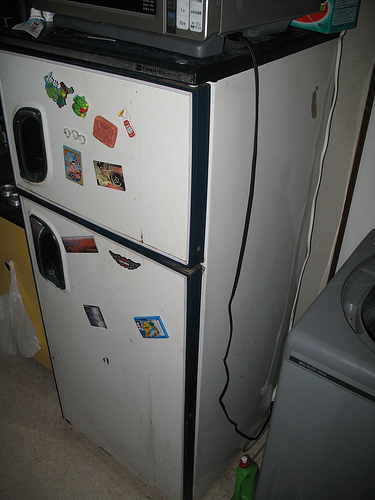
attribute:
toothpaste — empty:
[15, 6, 73, 46]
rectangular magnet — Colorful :
[92, 157, 128, 193]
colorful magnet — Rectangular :
[91, 158, 128, 192]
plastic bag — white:
[2, 259, 40, 358]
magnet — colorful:
[62, 145, 83, 186]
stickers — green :
[21, 68, 106, 119]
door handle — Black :
[25, 210, 66, 293]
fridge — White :
[2, 19, 326, 497]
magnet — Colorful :
[144, 33, 239, 90]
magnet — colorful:
[134, 315, 168, 339]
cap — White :
[240, 457, 247, 463]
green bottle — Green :
[235, 465, 258, 498]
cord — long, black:
[196, 27, 279, 464]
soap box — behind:
[292, 0, 361, 35]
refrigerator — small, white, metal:
[0, 19, 346, 498]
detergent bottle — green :
[229, 449, 267, 492]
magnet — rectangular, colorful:
[78, 299, 118, 342]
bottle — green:
[220, 449, 269, 498]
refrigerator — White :
[9, 36, 279, 483]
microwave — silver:
[26, 0, 331, 58]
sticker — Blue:
[135, 315, 169, 339]